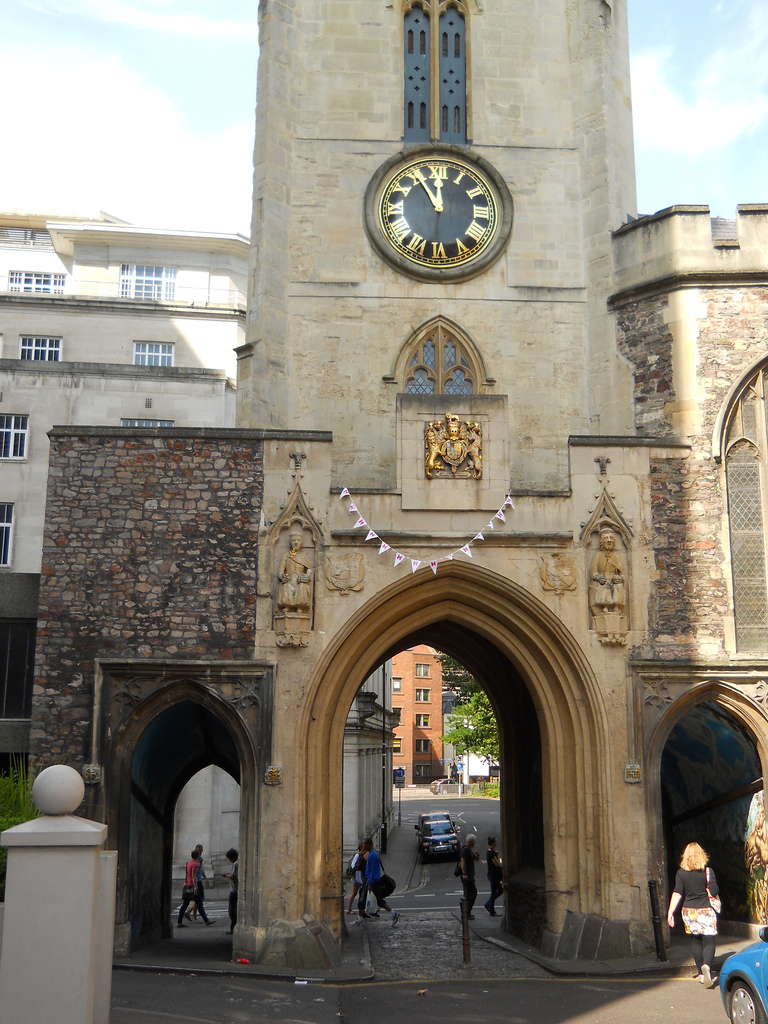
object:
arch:
[392, 312, 487, 395]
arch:
[105, 674, 257, 970]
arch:
[656, 684, 768, 949]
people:
[458, 833, 478, 921]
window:
[401, 0, 473, 143]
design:
[422, 411, 485, 480]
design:
[579, 454, 636, 649]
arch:
[294, 558, 612, 977]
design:
[266, 455, 327, 649]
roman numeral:
[427, 161, 448, 178]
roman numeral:
[453, 172, 467, 188]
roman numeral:
[466, 184, 485, 200]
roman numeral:
[473, 203, 490, 220]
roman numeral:
[466, 221, 488, 246]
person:
[350, 838, 401, 926]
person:
[483, 837, 507, 917]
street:
[349, 800, 555, 987]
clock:
[364, 142, 514, 285]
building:
[28, 0, 768, 970]